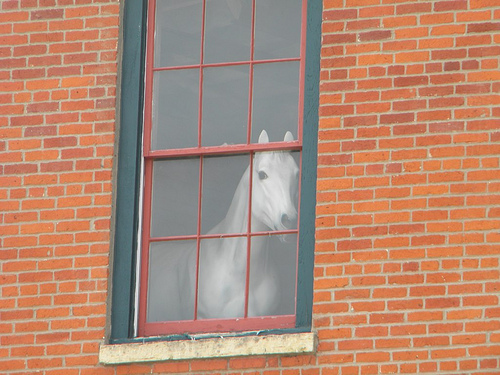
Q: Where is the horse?
A: Behind a window.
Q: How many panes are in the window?
A: Twelve.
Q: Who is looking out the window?
A: The horse.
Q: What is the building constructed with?
A: Brick.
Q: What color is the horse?
A: White.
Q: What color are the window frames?
A: Blue.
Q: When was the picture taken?
A: During the day.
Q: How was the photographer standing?
A: Below the window.